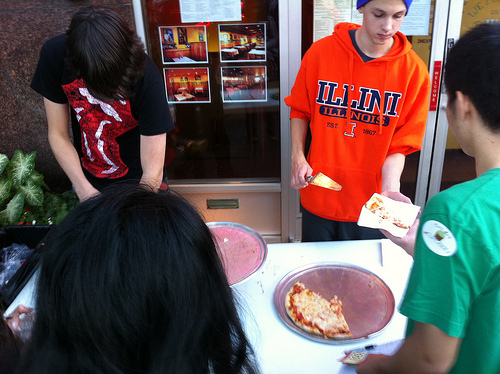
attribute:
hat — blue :
[356, 0, 412, 17]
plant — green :
[0, 149, 53, 225]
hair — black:
[64, 17, 172, 112]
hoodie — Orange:
[294, 35, 407, 181]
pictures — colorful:
[149, 19, 270, 111]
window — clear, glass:
[138, 2, 285, 175]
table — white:
[279, 238, 387, 265]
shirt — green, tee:
[395, 167, 498, 366]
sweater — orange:
[267, 15, 433, 235]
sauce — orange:
[284, 276, 352, 340]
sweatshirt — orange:
[288, 18, 433, 223]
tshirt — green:
[391, 168, 496, 373]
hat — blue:
[352, 0, 414, 10]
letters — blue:
[318, 80, 404, 121]